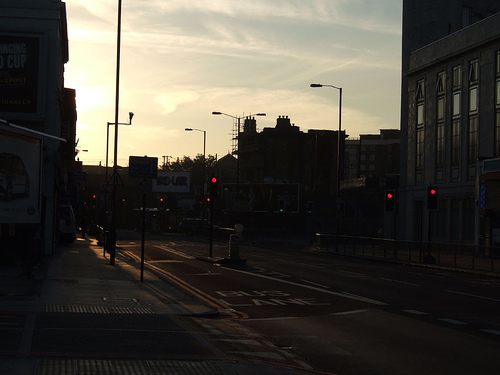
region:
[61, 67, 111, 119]
bright sun setting in sky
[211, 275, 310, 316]
white writing on pavement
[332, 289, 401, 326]
white lines painted on pavement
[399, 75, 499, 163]
row of windows on side of building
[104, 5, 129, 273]
black metal pole beside road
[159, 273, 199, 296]
yellow lines painted on pavement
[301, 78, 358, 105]
street light beside road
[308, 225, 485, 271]
metal guard railing beside road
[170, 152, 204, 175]
tree top with green leaves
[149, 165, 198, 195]
large white sign on side of building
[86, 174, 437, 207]
several traffic light glow red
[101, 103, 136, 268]
a traffic cam on the street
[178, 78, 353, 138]
tall street lights on a city street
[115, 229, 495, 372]
a black topped road in the city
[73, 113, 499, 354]
dawn on a city street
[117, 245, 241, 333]
a double yellow line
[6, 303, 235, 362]
access doors for delivery to a business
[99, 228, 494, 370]
One lane on the street is designated for buses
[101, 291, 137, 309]
a manhole in the sidewalk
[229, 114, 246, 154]
scaffolding on a building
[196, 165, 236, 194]
a lamb at night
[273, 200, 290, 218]
a lamb at night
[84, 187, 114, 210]
a lamb at night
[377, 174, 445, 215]
traffic lights are on red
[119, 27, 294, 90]
clouds cover the sky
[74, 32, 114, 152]
the sun is shining through the clouds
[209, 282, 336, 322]
words painted on the road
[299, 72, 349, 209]
street light is off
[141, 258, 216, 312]
lines painted on the road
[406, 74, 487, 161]
windows in the building are dark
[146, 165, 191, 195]
billboard on the side of the road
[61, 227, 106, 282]
sidewalk is empty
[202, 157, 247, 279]
traffic light in the middle of the road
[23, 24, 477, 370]
this is a city scene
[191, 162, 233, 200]
this is a traffic light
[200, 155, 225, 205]
traffic light is lit red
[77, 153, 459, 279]
multiple traffic lights on a street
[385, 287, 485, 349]
white dashed lines on street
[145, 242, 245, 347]
yellow lines on street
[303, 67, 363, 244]
this is a street light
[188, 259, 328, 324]
white writing on street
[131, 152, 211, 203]
a billboard in background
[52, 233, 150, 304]
this is the sidewalk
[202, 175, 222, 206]
A traffic light displaying a red light.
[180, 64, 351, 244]
Streetlights.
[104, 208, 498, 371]
The road.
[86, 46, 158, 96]
blue and yellow sky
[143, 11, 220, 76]
thin clouds in sky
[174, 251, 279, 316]
road is dark grey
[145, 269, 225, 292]
yellow lines on road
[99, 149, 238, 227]
traffic lights are red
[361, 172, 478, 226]
red traffic lights near building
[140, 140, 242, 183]
trees behind traffic lights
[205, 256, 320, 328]
white letters on road